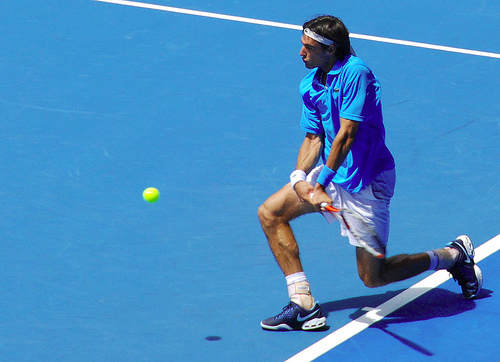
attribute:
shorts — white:
[306, 163, 395, 263]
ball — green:
[138, 184, 161, 205]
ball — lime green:
[132, 179, 170, 210]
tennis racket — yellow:
[305, 175, 400, 265]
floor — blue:
[2, 0, 497, 360]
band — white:
[305, 28, 345, 55]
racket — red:
[286, 184, 431, 258]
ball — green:
[128, 169, 208, 230]